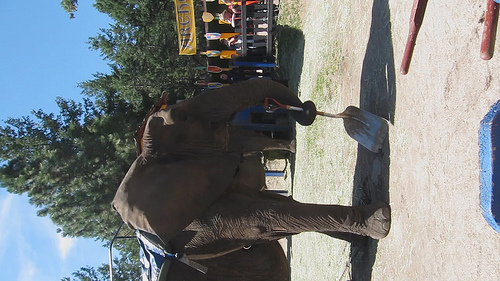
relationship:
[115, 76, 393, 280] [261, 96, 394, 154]
elephant holding shovel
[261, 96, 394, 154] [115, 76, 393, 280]
shovel held by elephant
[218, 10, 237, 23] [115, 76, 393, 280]
person watching elephant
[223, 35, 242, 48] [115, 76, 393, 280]
person watching elephant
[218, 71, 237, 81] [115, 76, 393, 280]
person watching elephant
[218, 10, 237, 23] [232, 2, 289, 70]
person behind fence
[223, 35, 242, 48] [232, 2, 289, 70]
person behind fence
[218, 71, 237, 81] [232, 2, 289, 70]
person behind fence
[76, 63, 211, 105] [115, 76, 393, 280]
tree behind elephant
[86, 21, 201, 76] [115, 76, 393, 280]
tree behind elephant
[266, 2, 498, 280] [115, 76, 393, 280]
sand under elephant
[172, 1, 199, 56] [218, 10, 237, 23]
banner above person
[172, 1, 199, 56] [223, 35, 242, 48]
banner above person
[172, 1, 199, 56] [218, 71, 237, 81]
banner above person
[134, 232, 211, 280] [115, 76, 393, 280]
blanket on elephant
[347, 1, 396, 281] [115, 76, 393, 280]
shadow of elephant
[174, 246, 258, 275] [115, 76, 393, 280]
harness on elephant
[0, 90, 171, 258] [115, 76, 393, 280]
tree behind elephant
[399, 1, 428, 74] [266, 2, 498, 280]
handle on sand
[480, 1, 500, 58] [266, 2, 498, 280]
handle on sand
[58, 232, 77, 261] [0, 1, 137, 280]
cloud in sky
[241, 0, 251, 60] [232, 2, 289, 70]
rail of fence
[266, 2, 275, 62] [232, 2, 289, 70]
rail of fence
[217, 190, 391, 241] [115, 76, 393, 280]
leg of elephant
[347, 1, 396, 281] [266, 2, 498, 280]
shadow on sand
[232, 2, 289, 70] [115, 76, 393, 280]
fence behind elephant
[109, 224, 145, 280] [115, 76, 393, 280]
coach on elephant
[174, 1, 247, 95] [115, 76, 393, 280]
shop behind elephant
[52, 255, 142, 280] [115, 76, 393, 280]
tree behind elephant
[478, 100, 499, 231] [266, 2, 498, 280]
object on sand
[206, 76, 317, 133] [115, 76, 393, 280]
trunk of elephant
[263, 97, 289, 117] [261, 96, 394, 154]
handle of shovel